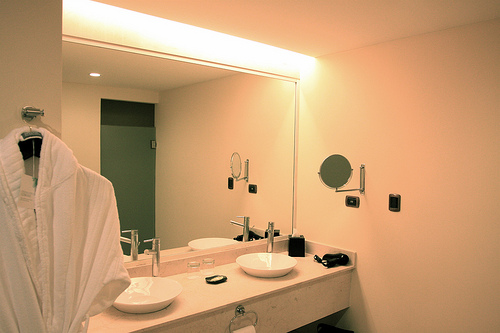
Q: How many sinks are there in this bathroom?
A: Two.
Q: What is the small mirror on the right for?
A: Shaving.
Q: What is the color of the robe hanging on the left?
A: White.